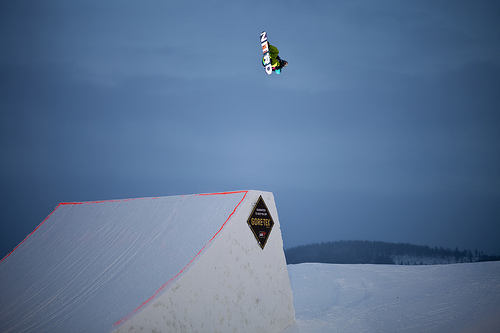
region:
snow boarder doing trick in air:
[247, 28, 284, 89]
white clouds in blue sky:
[0, 13, 60, 78]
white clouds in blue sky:
[32, 81, 100, 139]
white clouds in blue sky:
[30, 138, 122, 169]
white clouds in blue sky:
[104, 11, 201, 88]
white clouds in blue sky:
[177, 93, 244, 147]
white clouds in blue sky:
[304, 29, 394, 71]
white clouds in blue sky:
[187, 89, 254, 130]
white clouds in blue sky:
[271, 111, 342, 166]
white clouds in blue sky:
[355, 1, 453, 83]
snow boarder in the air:
[252, 13, 290, 79]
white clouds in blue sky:
[17, 58, 101, 118]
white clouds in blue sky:
[17, 124, 88, 156]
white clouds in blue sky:
[151, 116, 212, 151]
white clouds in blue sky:
[258, 145, 307, 180]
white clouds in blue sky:
[339, 94, 376, 129]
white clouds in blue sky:
[287, 150, 355, 187]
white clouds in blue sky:
[409, 180, 443, 210]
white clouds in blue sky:
[325, 56, 406, 124]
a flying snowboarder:
[257, 29, 289, 77]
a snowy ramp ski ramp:
[0, 188, 298, 330]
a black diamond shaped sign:
[243, 193, 276, 253]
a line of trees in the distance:
[282, 236, 499, 266]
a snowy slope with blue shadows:
[285, 260, 497, 332]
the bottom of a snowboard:
[258, 29, 271, 74]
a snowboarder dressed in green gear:
[257, 30, 289, 75]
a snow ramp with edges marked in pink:
[0, 188, 302, 332]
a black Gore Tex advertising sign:
[244, 193, 276, 252]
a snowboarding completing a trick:
[258, 30, 289, 76]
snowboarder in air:
[250, 13, 290, 90]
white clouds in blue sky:
[25, 26, 86, 81]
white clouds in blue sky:
[21, 85, 106, 159]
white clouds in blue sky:
[67, 19, 117, 94]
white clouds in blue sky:
[111, 118, 153, 158]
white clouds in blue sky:
[150, 32, 215, 127]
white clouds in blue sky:
[328, 2, 372, 66]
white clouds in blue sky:
[368, 85, 425, 165]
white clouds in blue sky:
[337, 115, 431, 167]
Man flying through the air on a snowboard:
[257, 29, 287, 76]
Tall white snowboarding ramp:
[1, 190, 301, 331]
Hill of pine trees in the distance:
[282, 239, 498, 264]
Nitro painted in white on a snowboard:
[258, 30, 273, 75]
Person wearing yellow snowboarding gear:
[257, 28, 287, 77]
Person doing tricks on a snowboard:
[259, 28, 289, 75]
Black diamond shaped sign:
[244, 192, 275, 252]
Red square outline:
[0, 188, 249, 331]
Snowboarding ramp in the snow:
[2, 186, 498, 331]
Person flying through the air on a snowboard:
[257, 28, 291, 77]